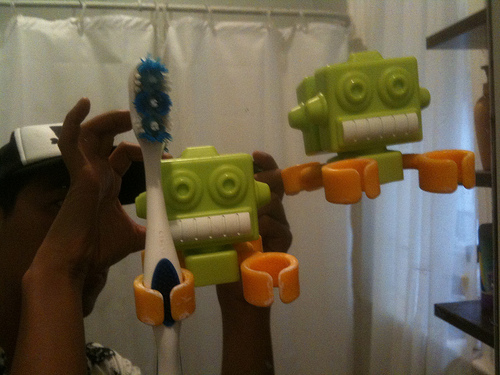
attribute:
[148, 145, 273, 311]
toy — green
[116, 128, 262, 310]
toy — green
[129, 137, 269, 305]
toy — green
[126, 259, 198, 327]
holder — orange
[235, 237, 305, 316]
holder — orange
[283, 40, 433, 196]
toy — green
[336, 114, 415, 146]
teeth — white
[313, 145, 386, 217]
hand — orange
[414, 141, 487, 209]
hand — orange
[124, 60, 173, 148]
bristles — blue, white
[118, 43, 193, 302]
toothbrush — white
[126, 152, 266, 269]
robot head — green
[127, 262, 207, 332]
hand — orange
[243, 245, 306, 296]
hand — orange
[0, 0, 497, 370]
shower curtain — white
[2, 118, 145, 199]
hat — black and white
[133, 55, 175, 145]
bristles — blue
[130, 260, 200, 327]
clip — orange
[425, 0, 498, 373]
shelf — dark, black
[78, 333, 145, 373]
sleeve — black and white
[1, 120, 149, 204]
hat — black and white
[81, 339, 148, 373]
shirt — black and white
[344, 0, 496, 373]
curtain — long, white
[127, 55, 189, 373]
toothbrush — blue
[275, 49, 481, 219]
toothbrush holder — robot 